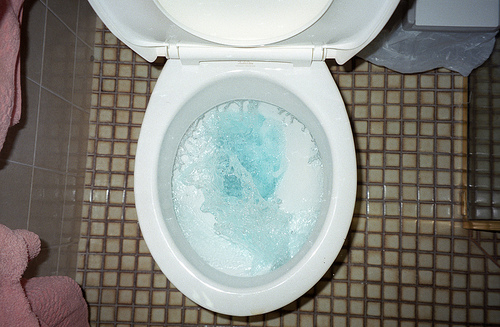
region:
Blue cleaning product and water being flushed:
[170, 96, 319, 290]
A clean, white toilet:
[83, 0, 398, 315]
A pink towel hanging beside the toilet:
[0, 0, 93, 325]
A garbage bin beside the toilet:
[356, 0, 499, 75]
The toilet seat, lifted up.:
[88, 0, 400, 69]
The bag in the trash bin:
[368, 17, 493, 78]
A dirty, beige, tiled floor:
[73, 15, 498, 324]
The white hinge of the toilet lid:
[167, 40, 335, 72]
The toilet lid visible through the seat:
[151, 0, 330, 52]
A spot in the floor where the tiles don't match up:
[464, 229, 499, 266]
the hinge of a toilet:
[165, 41, 183, 64]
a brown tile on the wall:
[36, 2, 78, 106]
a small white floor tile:
[96, 122, 116, 142]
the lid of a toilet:
[153, 0, 333, 43]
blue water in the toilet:
[198, 116, 288, 201]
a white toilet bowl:
[131, 57, 362, 322]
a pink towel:
[1, 220, 97, 322]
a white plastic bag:
[353, 26, 495, 81]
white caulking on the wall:
[39, 82, 77, 107]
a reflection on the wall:
[466, 74, 499, 219]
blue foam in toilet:
[132, 75, 382, 300]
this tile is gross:
[383, 228, 455, 296]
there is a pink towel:
[7, 230, 121, 323]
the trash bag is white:
[363, 27, 458, 77]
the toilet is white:
[236, 255, 331, 322]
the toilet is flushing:
[103, 43, 379, 290]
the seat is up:
[116, 80, 439, 247]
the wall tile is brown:
[18, 126, 130, 200]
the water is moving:
[158, 94, 392, 294]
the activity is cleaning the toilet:
[131, 52, 424, 299]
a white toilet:
[87, 0, 399, 317]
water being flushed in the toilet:
[168, 97, 324, 275]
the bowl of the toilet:
[133, 57, 358, 315]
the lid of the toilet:
[88, 0, 399, 65]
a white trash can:
[354, 0, 499, 77]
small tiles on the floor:
[76, 6, 498, 325]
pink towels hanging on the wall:
[0, 0, 90, 325]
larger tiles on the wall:
[0, 0, 95, 324]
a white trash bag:
[357, 9, 497, 78]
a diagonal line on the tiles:
[468, 228, 498, 275]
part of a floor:
[427, 96, 463, 110]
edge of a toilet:
[189, 290, 221, 320]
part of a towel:
[39, 282, 61, 296]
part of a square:
[369, 223, 393, 257]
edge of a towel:
[60, 272, 92, 297]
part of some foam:
[213, 207, 260, 258]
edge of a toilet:
[176, 237, 200, 264]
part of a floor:
[379, 197, 418, 268]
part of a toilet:
[181, 248, 221, 303]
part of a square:
[384, 255, 406, 282]